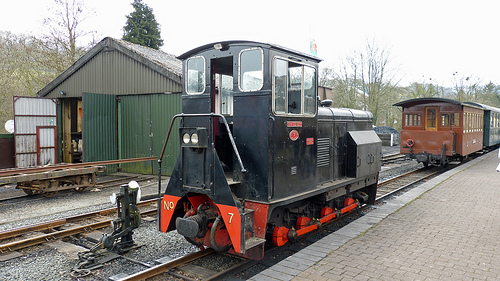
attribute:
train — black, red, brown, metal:
[165, 42, 380, 255]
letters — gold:
[162, 196, 175, 213]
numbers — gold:
[225, 210, 235, 222]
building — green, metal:
[38, 40, 183, 182]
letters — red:
[286, 116, 304, 142]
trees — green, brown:
[0, 10, 498, 139]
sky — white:
[3, 1, 497, 83]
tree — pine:
[123, 0, 164, 50]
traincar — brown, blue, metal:
[394, 95, 499, 171]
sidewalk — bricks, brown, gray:
[251, 153, 497, 281]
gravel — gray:
[2, 145, 397, 279]